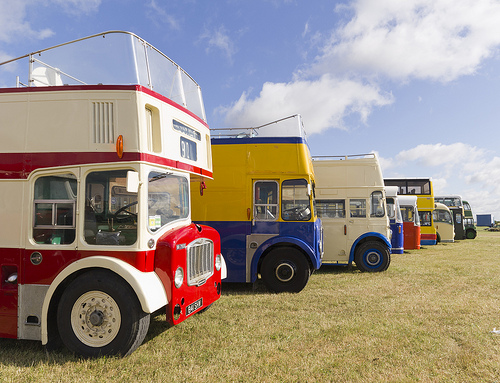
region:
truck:
[39, 58, 214, 379]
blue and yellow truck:
[232, 132, 330, 299]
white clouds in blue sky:
[202, 17, 286, 85]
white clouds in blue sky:
[206, 75, 248, 106]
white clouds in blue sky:
[216, 60, 251, 115]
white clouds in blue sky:
[249, 78, 296, 128]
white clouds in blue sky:
[295, 47, 343, 137]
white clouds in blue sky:
[339, 21, 390, 83]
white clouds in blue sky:
[381, 38, 442, 120]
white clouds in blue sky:
[421, 131, 469, 176]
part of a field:
[426, 302, 442, 317]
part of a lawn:
[347, 357, 354, 371]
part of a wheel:
[136, 320, 145, 335]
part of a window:
[93, 205, 116, 225]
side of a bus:
[63, 146, 82, 163]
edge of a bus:
[277, 200, 285, 228]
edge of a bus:
[382, 203, 387, 214]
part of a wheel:
[273, 266, 283, 279]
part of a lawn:
[361, 278, 371, 300]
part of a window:
[160, 200, 175, 227]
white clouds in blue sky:
[13, 6, 55, 34]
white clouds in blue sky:
[164, 13, 216, 55]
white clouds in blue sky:
[195, 6, 223, 57]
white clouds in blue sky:
[230, 30, 259, 112]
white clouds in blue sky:
[266, 21, 302, 109]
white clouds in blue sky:
[329, 7, 371, 89]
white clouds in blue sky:
[351, 19, 412, 109]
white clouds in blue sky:
[389, 91, 448, 171]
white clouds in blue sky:
[406, 55, 457, 122]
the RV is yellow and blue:
[216, 128, 317, 320]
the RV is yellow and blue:
[225, 110, 361, 380]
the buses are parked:
[29, 36, 485, 353]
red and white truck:
[55, 66, 210, 357]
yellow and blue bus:
[249, 136, 320, 293]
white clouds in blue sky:
[23, 5, 77, 40]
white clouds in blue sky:
[146, 6, 184, 47]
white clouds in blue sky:
[186, 19, 243, 63]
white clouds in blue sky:
[219, 12, 274, 114]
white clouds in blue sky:
[309, 16, 341, 94]